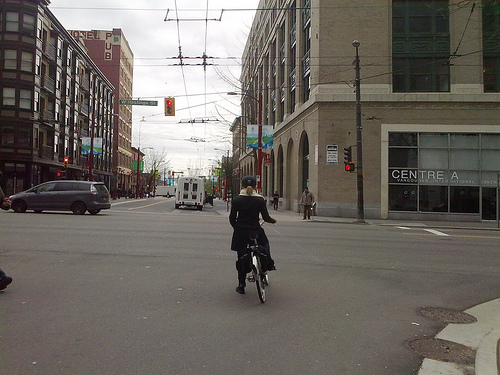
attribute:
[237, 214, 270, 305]
bike — clean, chrome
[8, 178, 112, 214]
car — grey, white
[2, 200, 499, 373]
street — city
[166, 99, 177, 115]
light — red, traffic, green, electric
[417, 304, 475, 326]
cover — manhole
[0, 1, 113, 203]
building — row, brick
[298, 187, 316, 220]
man — waiting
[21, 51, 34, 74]
window — large, glass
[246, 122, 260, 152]
sign — white, street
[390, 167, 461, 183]
lettering — white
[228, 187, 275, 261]
jacket — black